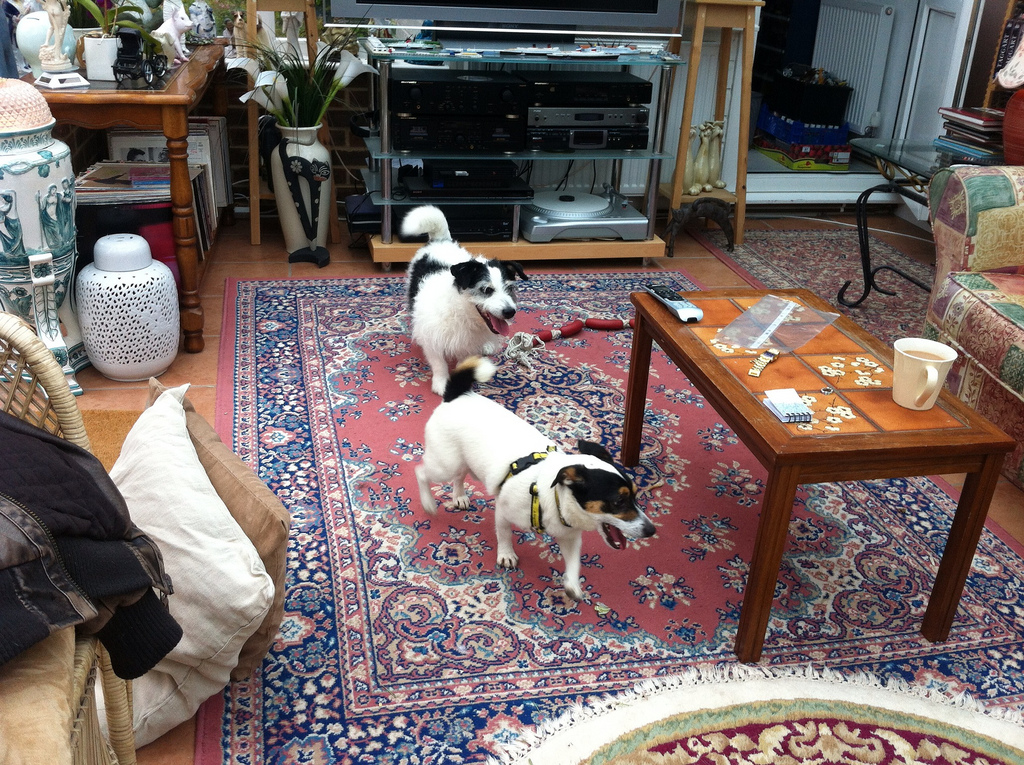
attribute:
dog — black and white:
[420, 355, 667, 592]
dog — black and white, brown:
[364, 180, 497, 392]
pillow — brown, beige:
[130, 339, 344, 679]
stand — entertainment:
[388, 37, 694, 229]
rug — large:
[244, 284, 365, 461]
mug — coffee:
[882, 338, 971, 416]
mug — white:
[882, 329, 955, 413]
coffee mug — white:
[889, 327, 963, 418]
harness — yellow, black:
[489, 450, 565, 571]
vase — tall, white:
[260, 107, 341, 267]